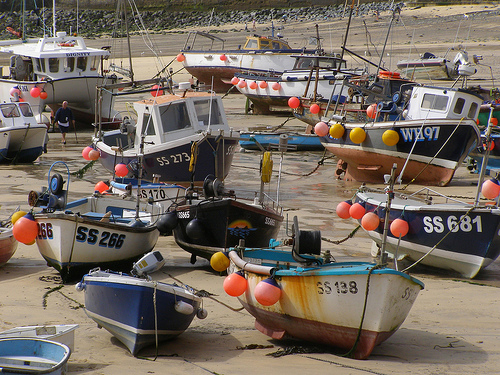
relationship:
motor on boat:
[130, 249, 166, 277] [82, 265, 203, 359]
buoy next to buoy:
[254, 283, 283, 312] [208, 249, 230, 275]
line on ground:
[39, 273, 88, 315] [0, 0, 500, 375]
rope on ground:
[232, 157, 335, 177] [0, 0, 500, 375]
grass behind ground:
[0, 1, 399, 40] [0, 0, 500, 375]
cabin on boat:
[406, 86, 483, 127] [315, 79, 483, 187]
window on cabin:
[418, 93, 451, 113] [406, 86, 483, 127]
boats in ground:
[0, 31, 500, 373] [0, 0, 500, 375]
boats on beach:
[0, 31, 500, 373] [3, 0, 500, 374]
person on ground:
[53, 97, 81, 148] [0, 0, 500, 375]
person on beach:
[53, 97, 81, 148] [3, 0, 500, 374]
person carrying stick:
[53, 97, 81, 148] [74, 127, 84, 149]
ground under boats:
[0, 0, 500, 375] [0, 31, 500, 373]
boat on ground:
[82, 265, 203, 359] [0, 31, 498, 373]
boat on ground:
[343, 180, 499, 281] [0, 31, 498, 373]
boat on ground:
[315, 79, 483, 187] [0, 31, 498, 373]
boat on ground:
[15, 176, 158, 281] [0, 31, 498, 373]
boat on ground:
[90, 93, 240, 189] [0, 31, 498, 373]